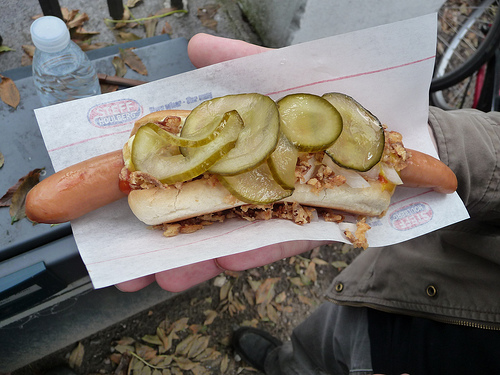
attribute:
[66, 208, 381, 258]
paper — wax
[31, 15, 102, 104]
water — bottled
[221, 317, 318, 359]
shoe — black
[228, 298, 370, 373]
pants — grey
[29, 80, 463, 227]
sandwich — one, peice, hotdog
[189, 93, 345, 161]
pickles — green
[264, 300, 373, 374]
pants — gray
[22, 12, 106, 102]
bottle — clear, plastic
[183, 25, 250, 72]
thumb — white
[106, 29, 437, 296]
hand — man's hand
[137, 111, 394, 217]
bun — short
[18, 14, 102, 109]
bottle — clear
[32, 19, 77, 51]
cap — white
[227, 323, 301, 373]
shoe — black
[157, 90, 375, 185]
pickles — green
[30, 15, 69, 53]
cap — white